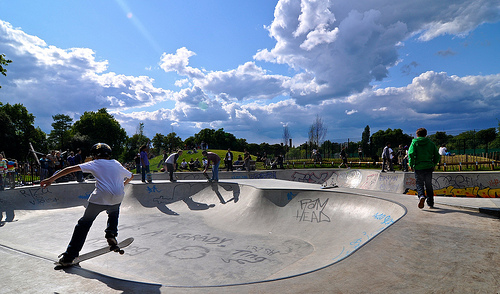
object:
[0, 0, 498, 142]
clouds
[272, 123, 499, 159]
bushes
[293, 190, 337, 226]
graffiti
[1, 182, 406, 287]
rink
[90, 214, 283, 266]
graffiti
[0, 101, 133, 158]
trees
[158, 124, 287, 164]
trees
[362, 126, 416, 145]
trees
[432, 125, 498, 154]
trees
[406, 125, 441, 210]
boy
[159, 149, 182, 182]
boy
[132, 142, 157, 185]
boy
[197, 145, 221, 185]
boy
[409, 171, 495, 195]
graffiti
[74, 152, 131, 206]
shirt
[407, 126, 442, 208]
person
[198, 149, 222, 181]
person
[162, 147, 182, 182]
person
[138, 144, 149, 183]
person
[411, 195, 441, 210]
sneaker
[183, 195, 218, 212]
shadow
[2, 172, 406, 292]
ramp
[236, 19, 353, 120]
cloudy sky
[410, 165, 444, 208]
blue jeans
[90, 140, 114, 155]
helmet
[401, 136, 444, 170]
jacket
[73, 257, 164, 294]
shadow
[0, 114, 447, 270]
people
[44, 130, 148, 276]
person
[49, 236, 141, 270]
skate board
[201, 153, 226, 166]
shirt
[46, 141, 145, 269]
boy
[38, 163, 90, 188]
arm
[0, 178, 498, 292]
ground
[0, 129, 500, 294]
skate park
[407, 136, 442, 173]
sweater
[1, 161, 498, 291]
park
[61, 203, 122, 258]
jeans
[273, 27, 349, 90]
sky's